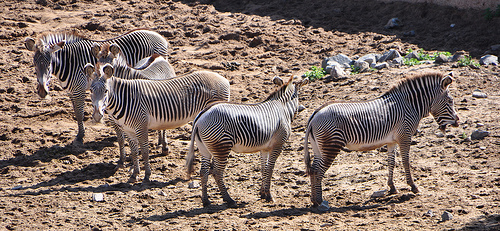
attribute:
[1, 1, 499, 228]
ground — dirt, dirty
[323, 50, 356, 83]
rock — grey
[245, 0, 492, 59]
mound — dirt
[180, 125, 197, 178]
tail — long, hanging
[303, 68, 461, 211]
zebra — striped, wild, cluster, standing, daytime, sunny, small, facing, group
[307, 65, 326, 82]
plant — patch, green